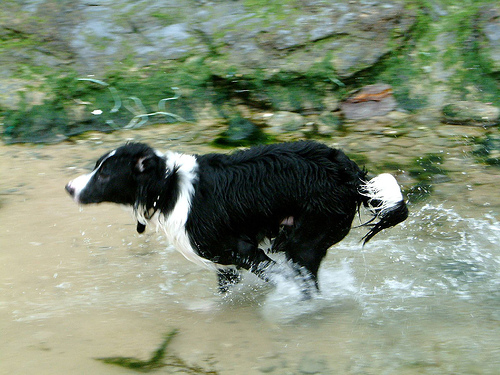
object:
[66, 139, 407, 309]
dog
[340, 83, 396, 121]
rock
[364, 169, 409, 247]
tail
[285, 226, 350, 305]
leg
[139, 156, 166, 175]
ear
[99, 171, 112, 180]
eye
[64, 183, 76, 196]
nose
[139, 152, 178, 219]
neck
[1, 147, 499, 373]
water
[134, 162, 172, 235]
collar